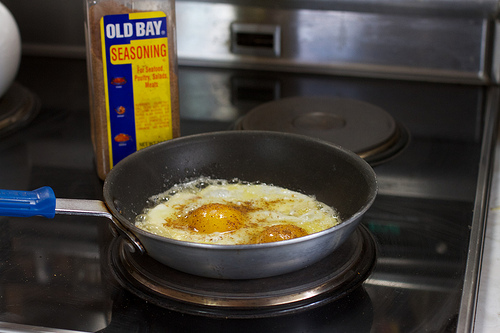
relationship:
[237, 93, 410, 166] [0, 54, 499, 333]
burner of stove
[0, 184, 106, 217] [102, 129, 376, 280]
handle of pan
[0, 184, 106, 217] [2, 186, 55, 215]
handle with protective covering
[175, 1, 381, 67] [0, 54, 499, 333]
reflection on stove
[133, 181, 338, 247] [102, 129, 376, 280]
eggs in pan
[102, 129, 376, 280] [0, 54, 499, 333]
pan on stove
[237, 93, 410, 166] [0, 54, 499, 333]
burner on stove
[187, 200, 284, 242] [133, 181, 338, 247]
seasoning on eggs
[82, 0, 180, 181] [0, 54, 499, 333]
seasoning on stove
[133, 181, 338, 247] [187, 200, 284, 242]
eggs with seasoning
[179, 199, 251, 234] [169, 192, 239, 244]
eggs of egg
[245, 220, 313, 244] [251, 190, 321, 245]
egg of egg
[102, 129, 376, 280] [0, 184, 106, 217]
pan with handle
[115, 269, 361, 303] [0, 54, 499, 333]
plate of stove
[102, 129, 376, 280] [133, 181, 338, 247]
pan with eggs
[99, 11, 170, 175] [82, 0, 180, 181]
label on seasoning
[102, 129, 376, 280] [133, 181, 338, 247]
pan cooking eggs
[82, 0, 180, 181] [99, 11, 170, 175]
seasoning with label